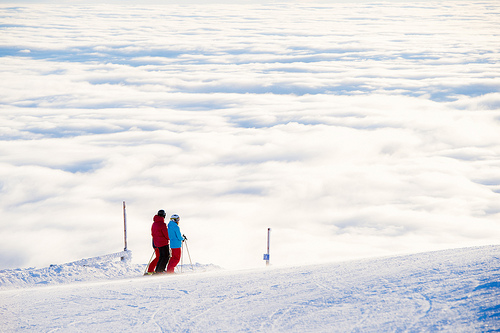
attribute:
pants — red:
[167, 250, 183, 275]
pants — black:
[147, 243, 169, 276]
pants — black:
[156, 245, 171, 273]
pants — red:
[165, 242, 188, 276]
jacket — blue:
[165, 220, 185, 249]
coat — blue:
[163, 219, 185, 251]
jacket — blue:
[149, 217, 167, 256]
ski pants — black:
[144, 244, 172, 274]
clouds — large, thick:
[1, 1, 498, 252]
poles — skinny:
[250, 211, 290, 281]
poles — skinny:
[108, 189, 147, 279]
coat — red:
[148, 214, 176, 247]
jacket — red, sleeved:
[138, 209, 165, 260]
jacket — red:
[150, 215, 169, 268]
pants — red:
[159, 248, 184, 275]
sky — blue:
[37, 52, 97, 72]